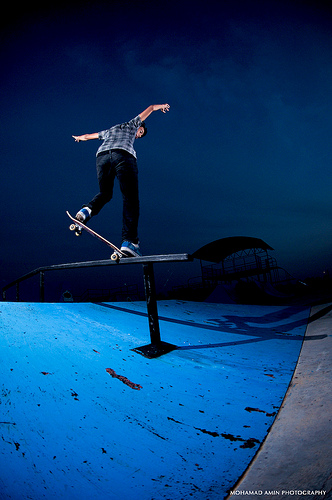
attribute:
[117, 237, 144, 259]
shoe — bright, blue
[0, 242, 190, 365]
rail — chipped, black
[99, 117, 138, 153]
shirt — blue, checkered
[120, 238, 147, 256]
shoe — blue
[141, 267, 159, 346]
pole — heavy, black, metal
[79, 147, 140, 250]
pants — long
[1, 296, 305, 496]
ramp — bright blue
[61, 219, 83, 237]
wheel — small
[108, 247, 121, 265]
wheel — small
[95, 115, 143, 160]
shirt — plaid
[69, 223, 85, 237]
wheels — back